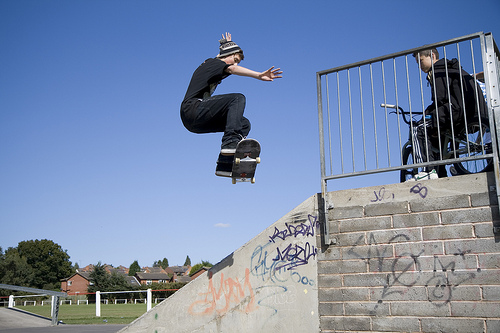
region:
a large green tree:
[13, 235, 68, 285]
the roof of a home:
[135, 267, 170, 277]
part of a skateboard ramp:
[0, 296, 80, 327]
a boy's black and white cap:
[216, 30, 241, 57]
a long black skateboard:
[229, 137, 261, 186]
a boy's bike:
[383, 102, 484, 178]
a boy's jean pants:
[176, 91, 252, 147]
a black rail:
[312, 32, 489, 193]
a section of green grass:
[25, 296, 142, 327]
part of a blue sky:
[0, 0, 170, 63]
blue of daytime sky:
[1, 2, 498, 264]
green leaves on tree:
[6, 239, 74, 289]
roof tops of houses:
[78, 264, 198, 287]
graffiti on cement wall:
[175, 209, 319, 331]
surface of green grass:
[19, 300, 156, 325]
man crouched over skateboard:
[179, 32, 281, 184]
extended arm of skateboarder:
[211, 42, 284, 84]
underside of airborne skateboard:
[231, 139, 261, 185]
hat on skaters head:
[216, 37, 244, 62]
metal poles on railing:
[318, 34, 493, 188]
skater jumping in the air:
[170, 19, 275, 203]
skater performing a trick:
[157, 13, 298, 205]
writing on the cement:
[188, 215, 327, 332]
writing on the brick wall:
[339, 218, 478, 325]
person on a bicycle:
[380, 34, 499, 191]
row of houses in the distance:
[52, 240, 208, 317]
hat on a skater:
[210, 28, 246, 60]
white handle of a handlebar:
[375, 94, 397, 115]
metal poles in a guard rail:
[305, 54, 495, 169]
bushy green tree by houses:
[5, 218, 72, 295]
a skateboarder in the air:
[173, 30, 283, 185]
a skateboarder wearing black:
[175, 30, 280, 185]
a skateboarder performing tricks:
[172, 25, 282, 182]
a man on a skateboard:
[180, 26, 285, 181]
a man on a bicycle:
[375, 45, 495, 175]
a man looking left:
[375, 41, 496, 176]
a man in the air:
[175, 31, 290, 178]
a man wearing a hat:
[179, 32, 284, 185]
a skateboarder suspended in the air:
[170, 28, 285, 185]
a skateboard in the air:
[227, 136, 264, 185]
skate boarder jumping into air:
[175, 29, 291, 191]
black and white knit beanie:
[215, 36, 244, 61]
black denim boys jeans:
[174, 84, 260, 154]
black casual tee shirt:
[179, 55, 235, 110]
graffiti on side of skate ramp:
[174, 207, 316, 330]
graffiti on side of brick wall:
[340, 183, 485, 329]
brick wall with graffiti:
[317, 166, 499, 331]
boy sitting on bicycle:
[373, 38, 498, 182]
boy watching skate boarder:
[376, 38, 497, 189]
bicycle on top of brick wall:
[376, 100, 498, 187]